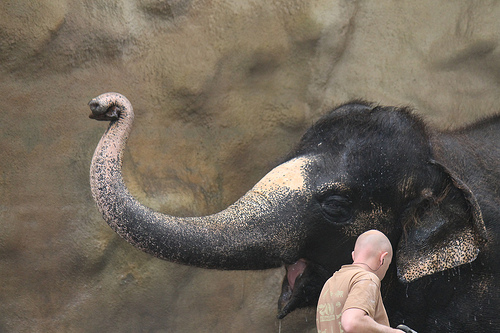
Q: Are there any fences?
A: No, there are no fences.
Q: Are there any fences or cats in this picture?
A: No, there are no fences or cats.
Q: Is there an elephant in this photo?
A: Yes, there is an elephant.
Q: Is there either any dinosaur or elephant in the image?
A: Yes, there is an elephant.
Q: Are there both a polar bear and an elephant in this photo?
A: No, there is an elephant but no polar bears.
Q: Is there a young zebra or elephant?
A: Yes, there is a young elephant.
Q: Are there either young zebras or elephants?
A: Yes, there is a young elephant.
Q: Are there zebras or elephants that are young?
A: Yes, the elephant is young.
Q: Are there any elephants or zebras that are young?
A: Yes, the elephant is young.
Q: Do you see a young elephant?
A: Yes, there is a young elephant.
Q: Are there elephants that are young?
A: Yes, there is an elephant that is young.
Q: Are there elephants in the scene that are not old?
A: Yes, there is an young elephant.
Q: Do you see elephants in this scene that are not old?
A: Yes, there is an young elephant.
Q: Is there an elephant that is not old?
A: Yes, there is an young elephant.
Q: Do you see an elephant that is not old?
A: Yes, there is an young elephant.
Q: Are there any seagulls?
A: No, there are no seagulls.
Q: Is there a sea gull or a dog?
A: No, there are no seagulls or dogs.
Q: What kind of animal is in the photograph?
A: The animal is an elephant.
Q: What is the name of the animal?
A: The animal is an elephant.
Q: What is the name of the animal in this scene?
A: The animal is an elephant.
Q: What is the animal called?
A: The animal is an elephant.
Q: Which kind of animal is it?
A: The animal is an elephant.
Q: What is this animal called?
A: This is an elephant.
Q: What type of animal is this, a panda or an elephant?
A: This is an elephant.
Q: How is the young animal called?
A: The animal is an elephant.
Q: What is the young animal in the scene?
A: The animal is an elephant.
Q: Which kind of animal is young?
A: The animal is an elephant.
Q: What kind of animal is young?
A: The animal is an elephant.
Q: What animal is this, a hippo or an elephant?
A: This is an elephant.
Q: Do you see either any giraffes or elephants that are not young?
A: No, there is an elephant but it is young.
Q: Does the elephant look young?
A: Yes, the elephant is young.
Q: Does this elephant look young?
A: Yes, the elephant is young.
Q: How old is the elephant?
A: The elephant is young.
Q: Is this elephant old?
A: No, the elephant is young.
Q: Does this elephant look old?
A: No, the elephant is young.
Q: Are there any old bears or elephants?
A: No, there is an elephant but it is young.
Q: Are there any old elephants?
A: No, there is an elephant but it is young.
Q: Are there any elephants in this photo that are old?
A: No, there is an elephant but it is young.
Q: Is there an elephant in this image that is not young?
A: No, there is an elephant but it is young.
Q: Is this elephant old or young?
A: The elephant is young.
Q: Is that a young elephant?
A: Yes, that is a young elephant.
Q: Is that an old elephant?
A: No, that is a young elephant.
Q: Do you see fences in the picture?
A: No, there are no fences.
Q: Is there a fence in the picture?
A: No, there are no fences.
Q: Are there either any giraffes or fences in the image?
A: No, there are no fences or giraffes.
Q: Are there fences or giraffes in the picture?
A: No, there are no fences or giraffes.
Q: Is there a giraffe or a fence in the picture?
A: No, there are no fences or giraffes.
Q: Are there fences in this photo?
A: No, there are no fences.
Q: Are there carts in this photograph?
A: No, there are no carts.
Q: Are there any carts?
A: No, there are no carts.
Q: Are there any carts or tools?
A: No, there are no carts or tools.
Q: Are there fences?
A: No, there are no fences.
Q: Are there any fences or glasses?
A: No, there are no fences or glasses.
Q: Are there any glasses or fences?
A: No, there are no fences or glasses.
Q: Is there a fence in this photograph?
A: No, there are no fences.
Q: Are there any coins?
A: No, there are no coins.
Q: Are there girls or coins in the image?
A: No, there are no coins or girls.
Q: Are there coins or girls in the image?
A: No, there are no coins or girls.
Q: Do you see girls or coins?
A: No, there are no coins or girls.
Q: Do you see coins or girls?
A: No, there are no coins or girls.